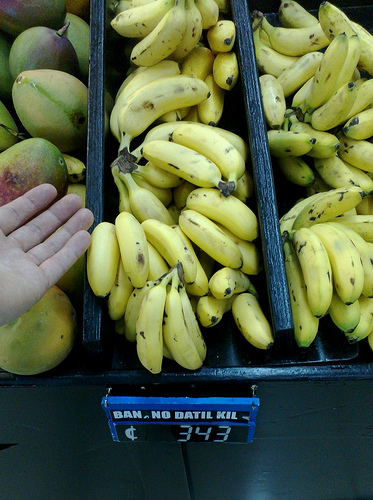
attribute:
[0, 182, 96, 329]
hand — human, caucasian, palm up, open palmed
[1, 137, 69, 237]
fruit — green, red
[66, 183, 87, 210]
fruit — green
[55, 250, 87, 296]
fruit — green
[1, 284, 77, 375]
fruit — green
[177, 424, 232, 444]
price — lettering, white, for bananas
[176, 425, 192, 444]
number — 3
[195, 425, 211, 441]
number — 4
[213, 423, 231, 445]
number — 3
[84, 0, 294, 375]
bin — black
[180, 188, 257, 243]
banana — bright yellow, small, ripe yellow, yellow, for sale, displayed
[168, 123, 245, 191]
banana — bright yellow, small, ripe yellow, yellow, for sale, displayed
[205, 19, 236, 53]
banana — bright yellow, small, ripe yellow, yellow, for sale, displayed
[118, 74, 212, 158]
banana — small, ripe yellow, yellow, for sale, displayed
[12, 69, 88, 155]
fruit — green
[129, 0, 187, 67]
banana — bright yellow, small, ripe yellow, yellow, for sale, displayed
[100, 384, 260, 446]
price sign — blue, black, displaying price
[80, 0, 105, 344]
seperator — wood, dark colored, wooden, painted wooden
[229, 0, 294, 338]
seperator — wood, dark colored, wooden, painted wooden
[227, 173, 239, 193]
stem — small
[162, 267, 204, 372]
banana — bright yellow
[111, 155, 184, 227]
bunch — bright yellow, of bananas, yellow, of fruit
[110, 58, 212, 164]
bunch — bright yellow, of bananas, yellow, of fruit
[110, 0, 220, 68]
bunch — bright yellow, of bananas, yellow, of fruit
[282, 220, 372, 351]
bunch — bright yellow, of bananas, yellow, of fruit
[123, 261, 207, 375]
bunch — bright yellow, of bananas, yellow, of fruit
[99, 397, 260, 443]
frame — blue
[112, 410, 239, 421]
writing — white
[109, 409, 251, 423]
background — black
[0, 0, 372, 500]
fruit stand — small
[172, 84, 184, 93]
spot — black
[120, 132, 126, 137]
spot — black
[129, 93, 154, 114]
spot — black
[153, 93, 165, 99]
spot — black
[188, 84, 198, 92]
spot — black